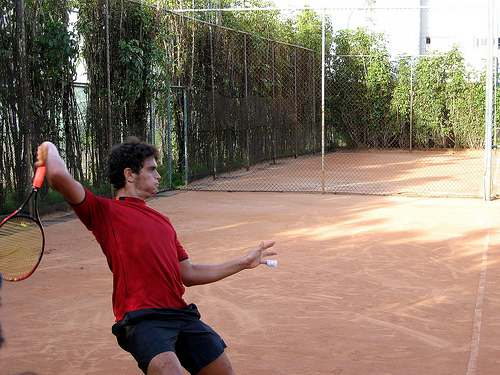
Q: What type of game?
A: Tennis.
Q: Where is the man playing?
A: Tennis court.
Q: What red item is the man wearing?
A: Shirt.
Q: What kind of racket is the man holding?
A: Tennis.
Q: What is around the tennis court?
A: Metal fence.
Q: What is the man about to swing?
A: Racket.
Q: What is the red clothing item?
A: Shirt.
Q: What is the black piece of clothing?
A: Shorts.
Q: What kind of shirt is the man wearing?
A: Red.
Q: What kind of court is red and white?
A: Tennis.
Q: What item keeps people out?
A: A fence.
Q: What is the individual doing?
A: Playing tennis.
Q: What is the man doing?
A: Playing tennis.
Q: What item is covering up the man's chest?
A: A shirt.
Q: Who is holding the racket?
A: A man.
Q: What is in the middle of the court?
A: A net.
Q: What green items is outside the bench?
A: A tree.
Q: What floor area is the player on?
A: Brown court.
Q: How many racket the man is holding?
A: One.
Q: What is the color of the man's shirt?
A: Red.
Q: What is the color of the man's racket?
A: Orange.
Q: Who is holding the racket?
A: The man.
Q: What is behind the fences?
A: Trees.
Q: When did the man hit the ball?
A: Earlier.